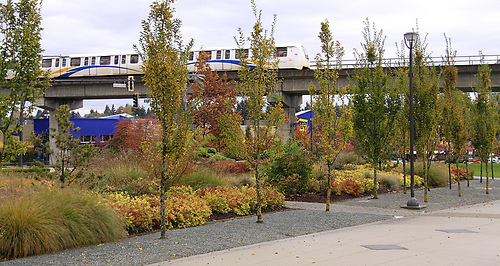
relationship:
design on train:
[45, 65, 144, 78] [5, 43, 313, 79]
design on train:
[182, 60, 257, 70] [5, 43, 313, 79]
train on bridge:
[5, 43, 313, 79] [1, 55, 500, 98]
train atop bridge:
[5, 43, 313, 79] [1, 55, 500, 98]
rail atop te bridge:
[310, 54, 499, 72] [1, 55, 500, 98]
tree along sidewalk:
[134, 0, 195, 238] [1, 177, 499, 266]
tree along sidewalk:
[217, 2, 285, 224] [1, 177, 499, 266]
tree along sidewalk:
[305, 18, 355, 214] [1, 177, 499, 266]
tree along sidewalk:
[353, 19, 403, 198] [1, 177, 499, 266]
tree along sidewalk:
[403, 25, 442, 201] [1, 177, 499, 266]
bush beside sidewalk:
[99, 190, 157, 235] [1, 177, 499, 266]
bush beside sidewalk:
[145, 187, 213, 228] [1, 177, 499, 266]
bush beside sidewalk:
[195, 183, 253, 219] [1, 177, 499, 266]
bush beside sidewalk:
[243, 181, 287, 212] [1, 177, 499, 266]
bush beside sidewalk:
[1, 190, 131, 258] [1, 177, 499, 266]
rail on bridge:
[310, 54, 499, 72] [1, 55, 500, 98]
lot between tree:
[387, 158, 499, 165] [403, 25, 442, 201]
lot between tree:
[387, 158, 499, 165] [438, 32, 478, 197]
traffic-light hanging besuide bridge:
[127, 75, 136, 91] [1, 55, 500, 98]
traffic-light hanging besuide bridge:
[133, 90, 140, 110] [1, 55, 500, 98]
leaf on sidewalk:
[105, 258, 111, 262] [1, 177, 499, 266]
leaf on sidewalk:
[79, 250, 86, 258] [1, 177, 499, 266]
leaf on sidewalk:
[96, 240, 107, 248] [1, 177, 499, 266]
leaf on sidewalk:
[137, 246, 145, 251] [1, 177, 499, 266]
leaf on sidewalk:
[153, 241, 159, 246] [1, 177, 499, 266]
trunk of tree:
[162, 125, 166, 242] [134, 0, 195, 238]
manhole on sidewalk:
[361, 241, 409, 254] [1, 177, 499, 266]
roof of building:
[99, 112, 146, 119] [33, 118, 141, 151]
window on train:
[100, 55, 110, 65] [5, 43, 313, 79]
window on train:
[71, 58, 81, 68] [5, 43, 313, 79]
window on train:
[131, 54, 139, 63] [5, 43, 313, 79]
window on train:
[41, 58, 54, 68] [5, 43, 313, 79]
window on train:
[275, 48, 287, 58] [5, 43, 313, 79]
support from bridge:
[33, 94, 85, 170] [1, 55, 500, 98]